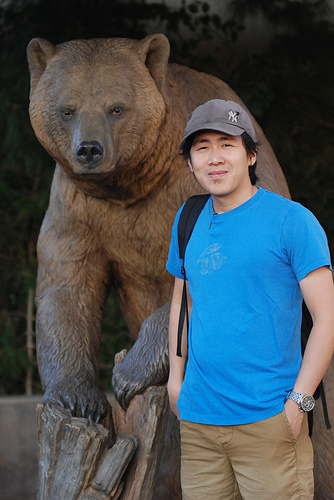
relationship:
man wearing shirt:
[166, 100, 333, 496] [165, 187, 333, 427]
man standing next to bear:
[166, 100, 333, 496] [26, 34, 294, 423]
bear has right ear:
[26, 34, 294, 423] [136, 32, 171, 90]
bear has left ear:
[26, 34, 294, 423] [27, 37, 57, 88]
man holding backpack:
[166, 100, 333, 496] [176, 193, 333, 438]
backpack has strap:
[176, 193, 333, 438] [174, 193, 210, 359]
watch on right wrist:
[288, 390, 317, 413] [285, 389, 316, 417]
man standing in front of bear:
[166, 100, 333, 496] [26, 34, 294, 423]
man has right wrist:
[166, 100, 333, 496] [285, 389, 316, 417]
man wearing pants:
[166, 100, 333, 496] [178, 409, 314, 498]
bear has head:
[26, 34, 294, 423] [27, 34, 169, 176]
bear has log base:
[26, 34, 294, 423] [36, 349, 332, 500]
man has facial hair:
[166, 100, 333, 496] [211, 175, 223, 185]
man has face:
[166, 100, 333, 496] [191, 133, 238, 196]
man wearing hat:
[166, 100, 333, 496] [176, 100, 258, 145]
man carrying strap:
[166, 100, 333, 496] [174, 193, 210, 359]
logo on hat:
[228, 109, 240, 126] [176, 100, 258, 145]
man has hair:
[166, 100, 333, 496] [176, 129, 263, 187]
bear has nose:
[26, 34, 294, 423] [73, 141, 106, 166]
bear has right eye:
[26, 34, 294, 423] [108, 103, 126, 117]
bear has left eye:
[26, 34, 294, 423] [60, 105, 73, 119]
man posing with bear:
[166, 100, 333, 496] [26, 34, 294, 423]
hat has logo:
[176, 100, 258, 145] [228, 109, 240, 126]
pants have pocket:
[178, 409, 314, 498] [275, 411, 296, 448]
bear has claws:
[26, 34, 294, 423] [56, 396, 104, 423]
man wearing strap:
[166, 100, 333, 496] [174, 193, 210, 359]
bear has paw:
[26, 34, 294, 423] [42, 382, 113, 421]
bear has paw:
[26, 34, 294, 423] [110, 359, 166, 411]